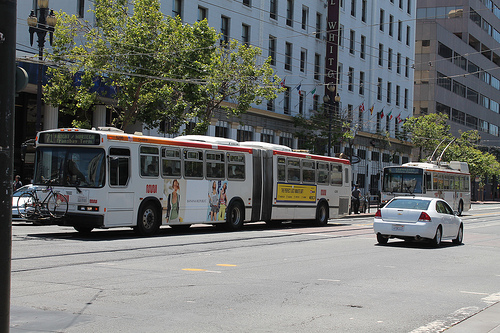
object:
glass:
[218, 13, 232, 45]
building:
[15, 1, 417, 202]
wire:
[21, 50, 495, 83]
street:
[15, 234, 481, 320]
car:
[373, 194, 468, 248]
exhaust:
[413, 232, 420, 244]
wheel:
[135, 199, 163, 236]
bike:
[17, 177, 67, 225]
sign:
[325, 0, 338, 111]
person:
[352, 181, 360, 215]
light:
[86, 204, 94, 213]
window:
[106, 146, 132, 187]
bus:
[33, 128, 351, 232]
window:
[139, 146, 160, 177]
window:
[160, 145, 183, 179]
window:
[181, 147, 202, 180]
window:
[204, 150, 224, 180]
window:
[227, 151, 246, 182]